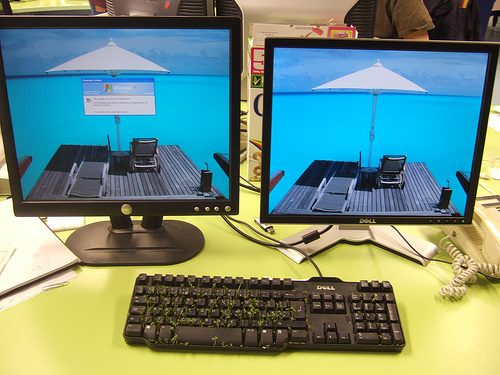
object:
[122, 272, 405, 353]
keyboard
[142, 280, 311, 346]
greenery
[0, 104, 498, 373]
desk